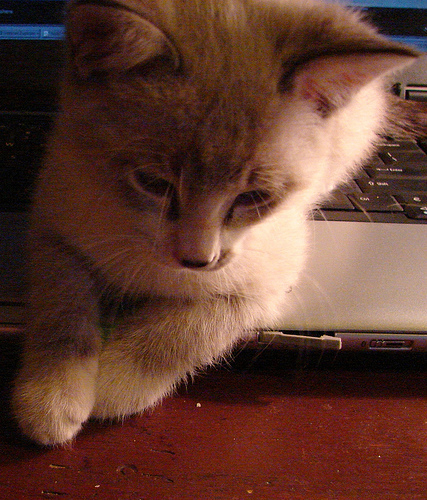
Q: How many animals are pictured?
A: One.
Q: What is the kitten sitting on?
A: Computer.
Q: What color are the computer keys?
A: Black.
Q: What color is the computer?
A: Grey.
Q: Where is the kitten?
A: On the laptop computer.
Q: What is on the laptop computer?
A: A kitten.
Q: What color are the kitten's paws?
A: White.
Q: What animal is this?
A: A cat.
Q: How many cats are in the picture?
A: One.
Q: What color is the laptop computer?
A: Gray.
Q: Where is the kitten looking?
A: Down.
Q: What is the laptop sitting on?
A: A table.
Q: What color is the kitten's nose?
A: Black.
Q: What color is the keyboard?
A: Black.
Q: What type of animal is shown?
A: Cat.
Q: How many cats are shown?
A: 1.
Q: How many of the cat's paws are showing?
A: 2.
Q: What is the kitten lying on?
A: Laptop.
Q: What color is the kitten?
A: Gray and tan.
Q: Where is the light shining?
A: Right side of the kitten.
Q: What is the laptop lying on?
A: Desk.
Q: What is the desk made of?
A: Wood.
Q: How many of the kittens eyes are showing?
A: 2.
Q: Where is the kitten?
A: On the laptop.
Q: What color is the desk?
A: Brown.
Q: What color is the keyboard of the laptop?
A: Black.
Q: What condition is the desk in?
A: Scratched.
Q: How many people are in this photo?
A: None.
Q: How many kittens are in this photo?
A: 1.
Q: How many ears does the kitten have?
A: 2.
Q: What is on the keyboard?
A: A cat is on the keyboard.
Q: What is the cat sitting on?
A: The cat is on the laptop.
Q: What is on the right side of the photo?
A: The left ear of the cat is on the right side of the photo.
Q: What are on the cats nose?
A: The whiskers are on the cat's nose.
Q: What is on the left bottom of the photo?
A: The paw of a cat is on the left bottom part of the photo.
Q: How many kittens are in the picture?
A: One.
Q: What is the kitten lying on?
A: Laptop keyboard.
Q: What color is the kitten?
A: Grey and white.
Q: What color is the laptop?
A: Silver and black.